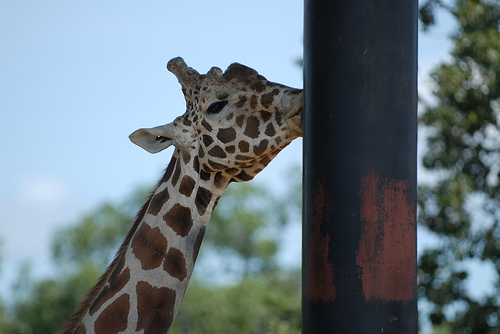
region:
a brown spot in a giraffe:
[135, 280, 177, 330]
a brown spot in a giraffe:
[89, 292, 131, 330]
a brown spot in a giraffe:
[88, 256, 132, 318]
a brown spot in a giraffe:
[161, 242, 189, 287]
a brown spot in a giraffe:
[131, 224, 166, 271]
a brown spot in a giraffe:
[162, 202, 194, 240]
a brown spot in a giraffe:
[141, 185, 169, 209]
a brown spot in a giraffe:
[181, 172, 197, 193]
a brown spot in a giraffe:
[191, 185, 214, 215]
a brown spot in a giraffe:
[170, 157, 181, 186]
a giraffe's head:
[22, 35, 328, 303]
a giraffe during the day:
[62, 20, 339, 301]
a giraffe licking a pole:
[29, 43, 319, 331]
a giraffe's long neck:
[105, 162, 195, 331]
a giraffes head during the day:
[144, 47, 303, 182]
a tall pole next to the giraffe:
[287, 5, 454, 323]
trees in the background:
[22, 180, 207, 330]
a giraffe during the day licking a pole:
[54, 24, 446, 316]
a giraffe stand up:
[21, 29, 453, 305]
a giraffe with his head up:
[54, 35, 380, 326]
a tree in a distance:
[53, 191, 110, 242]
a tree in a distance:
[15, 271, 69, 326]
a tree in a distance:
[197, 284, 232, 324]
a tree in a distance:
[218, 180, 290, 270]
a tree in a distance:
[231, 272, 295, 331]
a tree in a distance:
[71, 199, 132, 252]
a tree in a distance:
[427, 30, 494, 170]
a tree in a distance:
[420, 238, 495, 325]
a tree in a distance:
[433, 127, 498, 239]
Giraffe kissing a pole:
[49, 0, 435, 332]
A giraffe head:
[126, 53, 317, 187]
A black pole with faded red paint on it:
[300, 0, 420, 332]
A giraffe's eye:
[202, 99, 228, 116]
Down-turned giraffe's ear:
[126, 114, 193, 156]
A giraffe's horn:
[167, 54, 204, 90]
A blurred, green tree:
[421, 6, 496, 332]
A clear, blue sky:
[0, 0, 161, 117]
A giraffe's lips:
[283, 85, 302, 137]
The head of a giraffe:
[127, 53, 304, 183]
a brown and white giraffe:
[42, 15, 327, 328]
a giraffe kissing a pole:
[116, 54, 329, 179]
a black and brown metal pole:
[271, 8, 430, 330]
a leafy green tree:
[421, 2, 492, 332]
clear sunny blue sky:
[44, 5, 294, 194]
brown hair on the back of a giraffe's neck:
[62, 162, 172, 324]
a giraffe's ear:
[111, 115, 183, 163]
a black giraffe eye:
[197, 80, 242, 122]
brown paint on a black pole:
[352, 162, 420, 308]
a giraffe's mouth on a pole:
[270, 79, 315, 141]